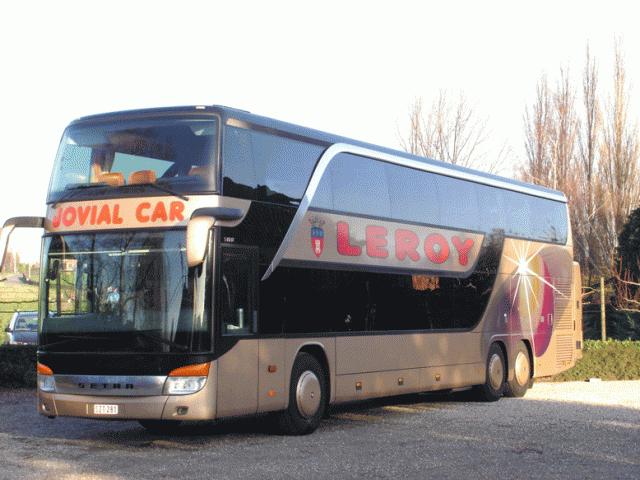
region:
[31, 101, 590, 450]
grey double decker bus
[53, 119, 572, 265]
second deck of the bus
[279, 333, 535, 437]
wheels on the bus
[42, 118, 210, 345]
front windshields on the bus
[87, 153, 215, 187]
seats on the top deck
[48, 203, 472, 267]
red lettering on the bus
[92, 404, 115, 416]
white license plate on the bus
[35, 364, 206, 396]
front lights on the bus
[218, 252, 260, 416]
door to the bus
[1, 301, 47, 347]
car parked beside the bus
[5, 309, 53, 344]
a parked silver car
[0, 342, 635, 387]
a green small hedge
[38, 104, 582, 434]
a parked double decker bus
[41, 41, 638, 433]
dead trees behind a bus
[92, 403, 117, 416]
a white license plate with black lettering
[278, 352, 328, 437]
a black tire with a silver hubcap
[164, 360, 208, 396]
a white and orange light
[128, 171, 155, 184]
an orange seat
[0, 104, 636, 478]
a bus parked on some gravel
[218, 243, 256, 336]
a small window with a silver handle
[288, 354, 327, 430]
front tire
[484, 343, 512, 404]
back tire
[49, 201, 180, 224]
writing on the bus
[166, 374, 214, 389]
clear headlight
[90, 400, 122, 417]
license plate on the bus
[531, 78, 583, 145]
a tall tree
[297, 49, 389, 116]
the sky is clear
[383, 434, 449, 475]
a shadow on the ground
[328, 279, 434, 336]
windows on the bus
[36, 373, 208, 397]
Headlights on front of bus.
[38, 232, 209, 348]
Front windshield of bus.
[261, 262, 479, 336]
Windows on side of bus.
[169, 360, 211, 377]
Orange left turn signal on front of bus.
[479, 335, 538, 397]
Two wheels on rear of bus.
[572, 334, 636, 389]
A low green hedge.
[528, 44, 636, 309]
Tall trees with few leaves.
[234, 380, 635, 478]
Gravel parking area.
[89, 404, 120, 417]
License plate on front of bus.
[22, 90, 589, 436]
double decker bus parked in a parking lot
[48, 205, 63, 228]
letter J on the double decker bus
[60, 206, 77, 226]
letter O on the double decker bus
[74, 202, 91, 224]
letter V on the double decker bus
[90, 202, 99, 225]
letter I on the double decker bus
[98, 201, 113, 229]
letter A on the double decker bus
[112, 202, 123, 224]
letter L on the double decker bus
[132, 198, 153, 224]
letter C on the double decker bus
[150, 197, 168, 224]
letter A on the double decker bus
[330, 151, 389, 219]
window on second story of bus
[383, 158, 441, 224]
window on second story of bus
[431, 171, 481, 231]
window on second story of bus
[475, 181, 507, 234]
window on second story of bus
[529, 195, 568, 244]
window on second story of bus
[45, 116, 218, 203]
window on second story of bus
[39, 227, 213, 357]
windshield on passenger bus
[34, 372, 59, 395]
headlight on passenger bus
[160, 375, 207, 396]
headlight on passenger bus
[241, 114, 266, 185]
a window on the bus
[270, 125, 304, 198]
a window on the bus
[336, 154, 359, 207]
a window on the bus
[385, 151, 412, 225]
a window on the bus